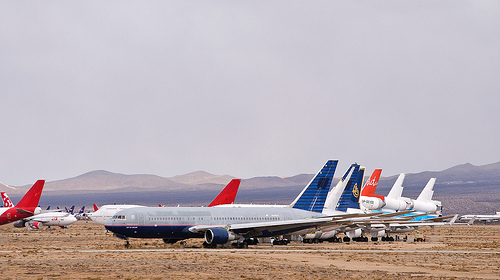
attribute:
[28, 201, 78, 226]
plane — white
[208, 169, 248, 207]
tail — red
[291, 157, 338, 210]
tail — blue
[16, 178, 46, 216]
tail — red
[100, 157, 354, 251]
plane — grey